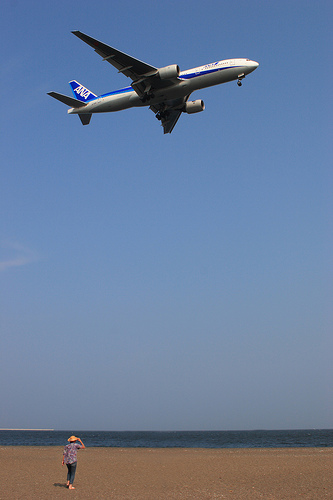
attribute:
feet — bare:
[50, 471, 82, 498]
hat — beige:
[66, 434, 80, 443]